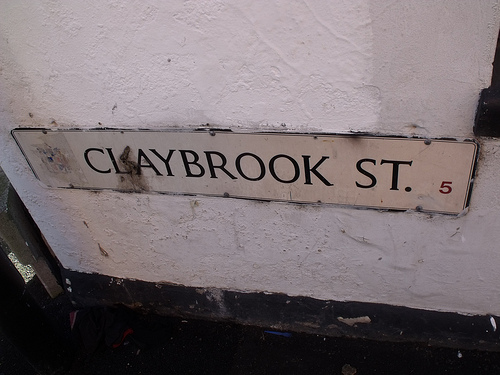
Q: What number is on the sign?
A: 5.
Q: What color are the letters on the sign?
A: Black.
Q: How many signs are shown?
A: One.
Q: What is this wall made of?
A: Stone.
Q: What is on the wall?
A: Signpost.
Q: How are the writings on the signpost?
A: Bold.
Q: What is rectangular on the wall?
A: Signpost.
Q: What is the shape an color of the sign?
A: Square and white.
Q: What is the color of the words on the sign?
A: Black.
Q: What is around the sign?
A: Black border.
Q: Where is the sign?
A: On a white wall.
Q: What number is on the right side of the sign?
A: 5.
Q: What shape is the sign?
A: Rectangular.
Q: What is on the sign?
A: Black spots.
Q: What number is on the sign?
A: 5.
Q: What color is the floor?
A: Black.